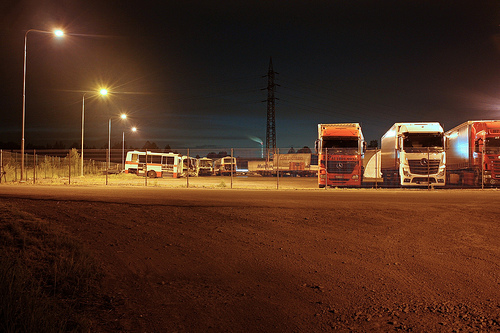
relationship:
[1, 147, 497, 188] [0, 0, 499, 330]
chainlink fence surrounding lot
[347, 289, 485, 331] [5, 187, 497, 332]
tracks in dirt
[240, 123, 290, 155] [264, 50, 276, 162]
smoke coming from chimney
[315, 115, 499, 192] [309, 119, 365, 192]
row of tractor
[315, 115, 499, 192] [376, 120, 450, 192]
row of truck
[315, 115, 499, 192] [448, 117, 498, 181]
row of truck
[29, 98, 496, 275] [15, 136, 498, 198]
lot with a fence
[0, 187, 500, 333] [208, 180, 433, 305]
dirt with stones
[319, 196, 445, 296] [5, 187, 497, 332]
tire tracks in dirt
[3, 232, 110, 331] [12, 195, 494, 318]
patch near dirt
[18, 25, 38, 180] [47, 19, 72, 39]
poles with lights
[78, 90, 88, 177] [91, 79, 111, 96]
pole with lights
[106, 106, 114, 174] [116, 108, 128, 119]
poles with lights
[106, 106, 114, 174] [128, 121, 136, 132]
poles with lights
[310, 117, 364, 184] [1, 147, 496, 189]
tractor parked behind chainlink fence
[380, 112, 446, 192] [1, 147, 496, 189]
tractor parked behind chainlink fence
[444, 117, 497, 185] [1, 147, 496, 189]
tractor parked behind chainlink fence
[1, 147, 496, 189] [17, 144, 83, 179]
chainlink fence with weeds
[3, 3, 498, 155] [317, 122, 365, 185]
sky above truck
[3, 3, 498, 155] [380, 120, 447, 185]
sky above truck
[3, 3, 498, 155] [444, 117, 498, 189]
sky above tractor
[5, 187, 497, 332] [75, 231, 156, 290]
dirt on ground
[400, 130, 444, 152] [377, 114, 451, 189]
window on front of truck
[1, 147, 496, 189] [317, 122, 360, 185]
chainlink fence in front of trucks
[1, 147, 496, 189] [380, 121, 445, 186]
chainlink fence in front of trucks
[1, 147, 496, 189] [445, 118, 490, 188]
chainlink fence in front of trucks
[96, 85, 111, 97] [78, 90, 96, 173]
light on a pole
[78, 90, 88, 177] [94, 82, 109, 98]
pole under a light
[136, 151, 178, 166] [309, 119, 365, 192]
windows on tractor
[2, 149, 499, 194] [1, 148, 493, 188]
pole of fence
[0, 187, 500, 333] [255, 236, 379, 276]
dirt on ground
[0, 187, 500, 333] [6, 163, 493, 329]
dirt on ground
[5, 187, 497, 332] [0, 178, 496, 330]
dirt on ground